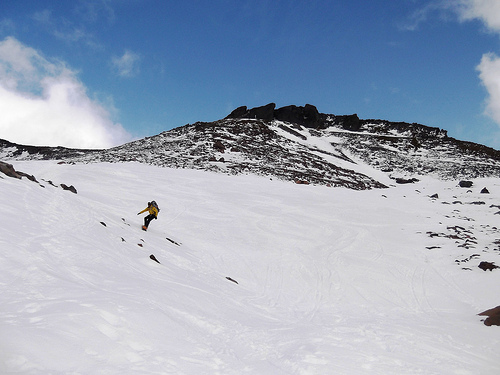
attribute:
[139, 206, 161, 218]
shirt — yellow 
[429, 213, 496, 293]
rocks — scattered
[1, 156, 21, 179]
rock — black 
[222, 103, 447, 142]
rocks — jagged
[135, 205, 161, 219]
jacket — yellow 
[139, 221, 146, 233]
shoe — red 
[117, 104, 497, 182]
hill — dome shaped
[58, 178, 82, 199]
rock — black 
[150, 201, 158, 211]
backpack — greenish 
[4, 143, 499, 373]
hillside — snow filled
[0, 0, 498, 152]
sky — clear, blue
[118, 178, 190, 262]
coat — yellow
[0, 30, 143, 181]
clouds — white 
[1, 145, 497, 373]
slope — snowy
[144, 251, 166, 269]
rock — black 